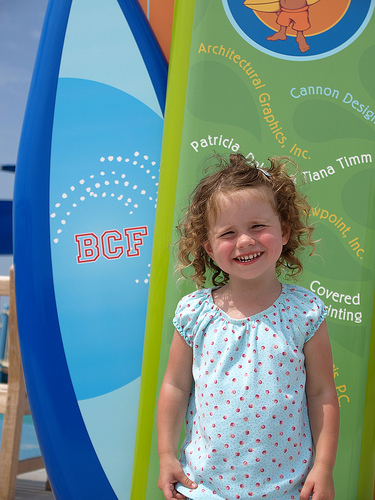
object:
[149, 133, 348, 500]
girl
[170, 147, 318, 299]
hair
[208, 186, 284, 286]
face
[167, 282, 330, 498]
shirt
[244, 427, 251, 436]
dot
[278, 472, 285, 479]
dot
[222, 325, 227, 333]
dot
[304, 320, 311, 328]
dot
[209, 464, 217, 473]
dot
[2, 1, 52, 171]
sky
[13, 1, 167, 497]
surfboard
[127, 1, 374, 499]
surfboard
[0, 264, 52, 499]
stand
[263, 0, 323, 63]
character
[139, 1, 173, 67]
surfboard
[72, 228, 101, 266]
letter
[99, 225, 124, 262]
letter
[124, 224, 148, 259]
letter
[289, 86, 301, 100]
letter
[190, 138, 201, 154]
letter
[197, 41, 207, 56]
letter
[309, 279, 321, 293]
letter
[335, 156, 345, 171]
letter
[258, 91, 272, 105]
letter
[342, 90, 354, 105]
letter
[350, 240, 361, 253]
letter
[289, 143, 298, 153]
letter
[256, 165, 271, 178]
ribbon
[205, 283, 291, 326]
collar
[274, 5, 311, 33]
shorts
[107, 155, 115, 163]
spot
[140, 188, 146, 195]
spot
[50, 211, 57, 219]
spot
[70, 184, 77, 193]
spot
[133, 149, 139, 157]
spot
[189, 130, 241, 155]
patricia